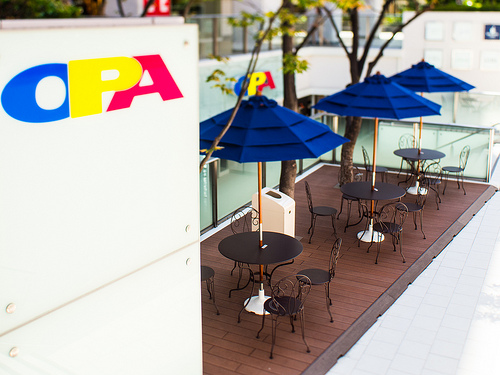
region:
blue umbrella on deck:
[331, 71, 448, 128]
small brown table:
[210, 225, 307, 291]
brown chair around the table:
[250, 266, 327, 352]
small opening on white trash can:
[265, 183, 290, 207]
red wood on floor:
[348, 259, 385, 294]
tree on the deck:
[341, 115, 369, 196]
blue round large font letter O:
[0, 60, 67, 123]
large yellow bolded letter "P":
[63, 56, 140, 118]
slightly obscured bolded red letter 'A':
[107, 55, 184, 113]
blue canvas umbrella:
[319, 67, 442, 120]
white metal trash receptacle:
[252, 183, 297, 238]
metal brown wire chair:
[304, 179, 337, 245]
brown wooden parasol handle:
[257, 163, 264, 248]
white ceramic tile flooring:
[411, 275, 498, 374]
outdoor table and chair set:
[305, 167, 410, 267]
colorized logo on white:
[1, 33, 198, 123]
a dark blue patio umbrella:
[198, 96, 349, 162]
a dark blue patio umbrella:
[308, 70, 442, 117]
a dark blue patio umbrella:
[387, 57, 475, 94]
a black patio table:
[218, 229, 300, 301]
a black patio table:
[340, 179, 409, 236]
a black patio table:
[393, 147, 446, 188]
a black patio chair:
[253, 269, 312, 358]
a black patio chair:
[297, 237, 341, 324]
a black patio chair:
[228, 204, 261, 286]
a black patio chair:
[200, 263, 220, 316]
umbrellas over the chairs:
[168, 50, 478, 182]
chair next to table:
[248, 263, 318, 334]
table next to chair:
[212, 214, 309, 285]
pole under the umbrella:
[223, 147, 291, 246]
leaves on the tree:
[272, 45, 314, 80]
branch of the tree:
[247, 37, 340, 137]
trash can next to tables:
[228, 184, 310, 233]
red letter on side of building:
[112, 41, 188, 119]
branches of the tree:
[308, 9, 454, 64]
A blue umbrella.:
[197, 95, 351, 157]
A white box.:
[247, 184, 296, 238]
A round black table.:
[217, 233, 302, 305]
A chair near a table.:
[294, 234, 346, 324]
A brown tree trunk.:
[276, 0, 299, 265]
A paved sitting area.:
[204, 165, 497, 374]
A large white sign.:
[0, 14, 202, 374]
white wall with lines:
[61, 156, 158, 323]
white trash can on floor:
[246, 183, 302, 228]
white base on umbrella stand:
[236, 280, 300, 328]